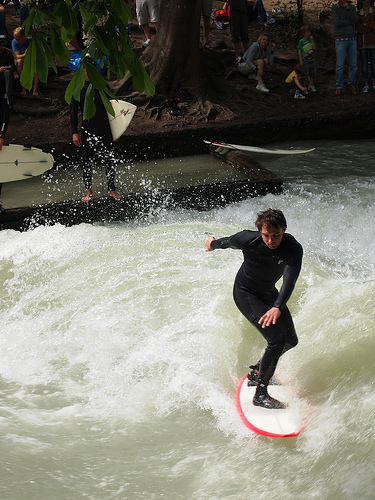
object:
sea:
[0, 189, 375, 499]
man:
[205, 209, 304, 410]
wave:
[2, 190, 372, 498]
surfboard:
[236, 366, 312, 448]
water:
[1, 134, 374, 498]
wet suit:
[209, 231, 300, 383]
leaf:
[76, 77, 104, 126]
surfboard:
[0, 142, 55, 187]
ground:
[1, 67, 374, 170]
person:
[11, 25, 38, 97]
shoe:
[253, 387, 286, 409]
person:
[69, 56, 121, 203]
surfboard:
[106, 99, 138, 142]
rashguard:
[210, 229, 304, 312]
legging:
[262, 326, 285, 384]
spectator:
[233, 4, 374, 97]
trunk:
[100, 2, 231, 126]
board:
[204, 140, 315, 155]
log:
[210, 144, 284, 188]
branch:
[20, 0, 150, 118]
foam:
[2, 222, 112, 278]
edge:
[236, 371, 296, 439]